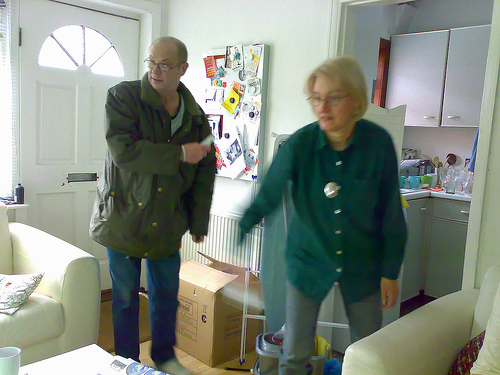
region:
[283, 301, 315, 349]
part of a trouser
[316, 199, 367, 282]
part of a shirt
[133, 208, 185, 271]
part of a jacket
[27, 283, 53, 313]
part of a chair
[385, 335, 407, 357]
part of a couch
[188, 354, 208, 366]
part of a floor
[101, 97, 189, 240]
man wearing a green jacket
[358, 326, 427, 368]
a white couch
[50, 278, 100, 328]
the couch is white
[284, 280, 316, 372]
the women is wearing pants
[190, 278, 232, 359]
a box on the floor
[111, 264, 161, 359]
man is wearing blue jeans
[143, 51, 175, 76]
man is wearing eye glasses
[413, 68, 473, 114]
the cabinets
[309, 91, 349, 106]
the women wearing eye glasses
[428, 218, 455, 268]
the cabinets are white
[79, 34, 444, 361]
A man and woman standing in the house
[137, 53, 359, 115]
Two peoples wearing spectacles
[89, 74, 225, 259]
A man wearing green color jacket and blue color jean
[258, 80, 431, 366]
A woman wearing blue color shirt and grey color pant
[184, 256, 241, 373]
Box behind the people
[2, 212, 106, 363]
White color sofa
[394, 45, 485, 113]
Racks behind the people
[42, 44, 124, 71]
Glass windows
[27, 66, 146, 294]
White color door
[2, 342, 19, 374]
A cup above the table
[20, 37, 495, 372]
Two people in a living room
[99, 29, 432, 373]
An old married couple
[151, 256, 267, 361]
A cardboard box on the floor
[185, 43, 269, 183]
A wall board with many notes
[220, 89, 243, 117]
A piece of yellow paper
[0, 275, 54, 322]
A throw pillow on the couch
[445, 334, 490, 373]
A small red pillow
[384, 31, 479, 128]
Two white cabinets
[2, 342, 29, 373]
A paper drinking cup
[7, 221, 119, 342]
A white couch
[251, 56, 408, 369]
lady wearing glasses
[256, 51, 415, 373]
lady wearing green shirt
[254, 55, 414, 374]
lady wearing denim jeans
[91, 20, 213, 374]
guy wearing glasses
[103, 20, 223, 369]
guy wearing green jacket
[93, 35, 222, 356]
guy wearing blue denim jeans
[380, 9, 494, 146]
white cabinets on wall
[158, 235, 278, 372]
brown box on floor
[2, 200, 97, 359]
white arm on white couch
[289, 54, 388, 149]
lady with shirt hair